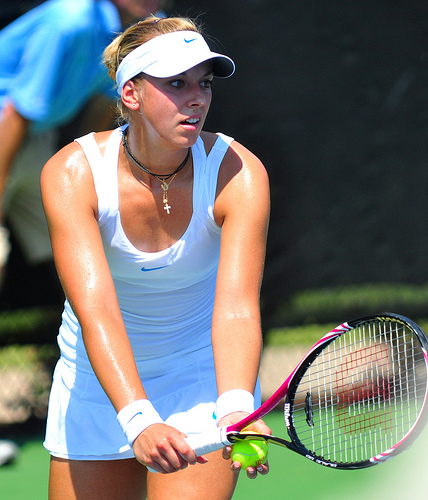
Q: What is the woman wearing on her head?
A: Visor.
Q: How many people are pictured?
A: 1.